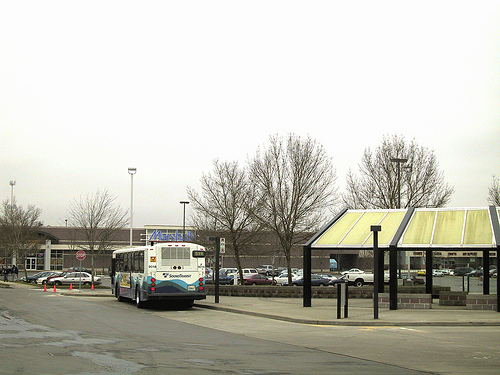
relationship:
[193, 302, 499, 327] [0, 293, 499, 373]
edge of a road